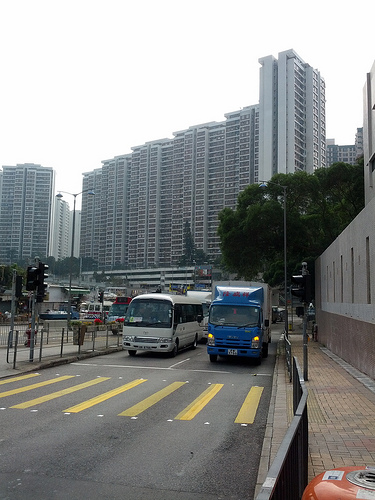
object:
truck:
[208, 281, 273, 364]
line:
[234, 385, 263, 425]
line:
[175, 382, 225, 421]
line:
[120, 381, 188, 417]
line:
[63, 377, 147, 413]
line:
[9, 376, 112, 411]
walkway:
[0, 371, 271, 427]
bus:
[123, 293, 204, 358]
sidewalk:
[294, 336, 375, 486]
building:
[78, 50, 326, 281]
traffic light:
[26, 262, 50, 303]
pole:
[29, 294, 35, 362]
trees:
[218, 159, 364, 288]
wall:
[314, 201, 375, 384]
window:
[226, 120, 240, 126]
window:
[240, 132, 249, 137]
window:
[240, 150, 249, 155]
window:
[240, 173, 249, 178]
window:
[225, 183, 235, 188]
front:
[207, 301, 264, 357]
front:
[122, 294, 174, 353]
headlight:
[254, 336, 260, 341]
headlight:
[208, 333, 215, 344]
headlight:
[159, 337, 167, 343]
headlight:
[123, 336, 130, 341]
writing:
[223, 290, 250, 297]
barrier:
[256, 332, 311, 500]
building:
[314, 64, 375, 387]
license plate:
[228, 348, 238, 354]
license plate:
[141, 345, 149, 349]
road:
[0, 324, 289, 499]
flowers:
[94, 318, 103, 323]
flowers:
[115, 317, 125, 322]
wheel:
[171, 341, 177, 358]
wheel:
[193, 335, 197, 348]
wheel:
[128, 350, 137, 355]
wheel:
[209, 354, 217, 363]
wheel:
[255, 357, 262, 365]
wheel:
[263, 343, 268, 358]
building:
[0, 162, 56, 268]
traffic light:
[292, 261, 313, 303]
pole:
[303, 300, 308, 381]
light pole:
[259, 177, 288, 339]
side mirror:
[265, 319, 270, 327]